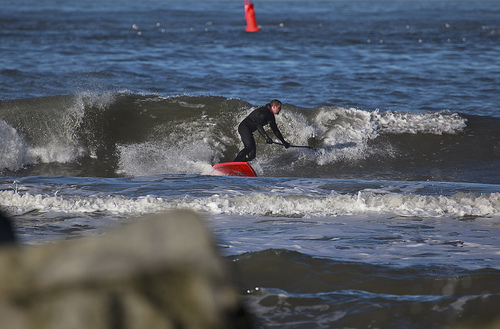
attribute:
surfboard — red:
[214, 153, 252, 177]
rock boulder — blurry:
[0, 202, 258, 324]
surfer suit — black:
[225, 104, 281, 164]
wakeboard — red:
[214, 160, 260, 179]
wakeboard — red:
[219, 158, 252, 177]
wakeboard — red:
[212, 156, 252, 174]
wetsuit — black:
[228, 106, 288, 165]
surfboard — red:
[211, 146, 251, 183]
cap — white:
[328, 93, 403, 155]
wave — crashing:
[395, 133, 455, 213]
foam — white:
[315, 184, 426, 245]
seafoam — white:
[320, 191, 410, 229]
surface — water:
[321, 222, 401, 259]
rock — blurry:
[51, 230, 199, 305]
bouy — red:
[226, 12, 284, 32]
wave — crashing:
[47, 149, 137, 203]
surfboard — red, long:
[210, 158, 281, 199]